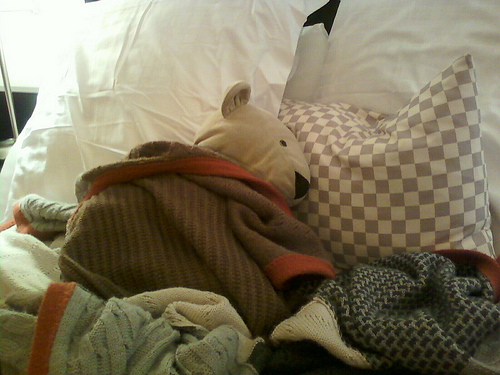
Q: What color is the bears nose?
A: Black.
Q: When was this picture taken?
A: During the day.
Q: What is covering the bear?
A: A blanket.